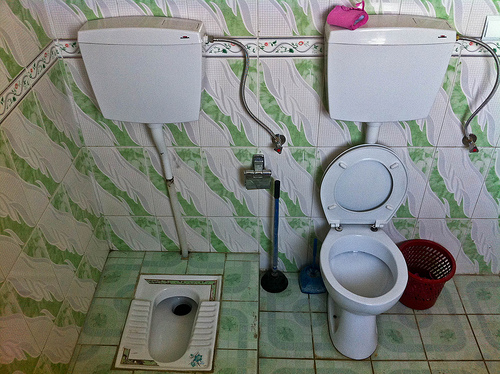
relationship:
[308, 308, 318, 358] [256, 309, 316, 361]
grout between tile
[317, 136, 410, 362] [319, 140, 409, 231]
toilet with lid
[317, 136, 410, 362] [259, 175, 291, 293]
toilet has plunger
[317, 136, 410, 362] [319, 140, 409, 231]
toilet has lid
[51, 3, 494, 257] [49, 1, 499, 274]
tile on wall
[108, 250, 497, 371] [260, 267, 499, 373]
tile on floor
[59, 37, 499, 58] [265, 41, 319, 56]
boarder has flowers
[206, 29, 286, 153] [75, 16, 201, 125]
pipe coming out of bathroom fixtures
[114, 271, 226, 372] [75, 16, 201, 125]
urinal has bathroom fixtures